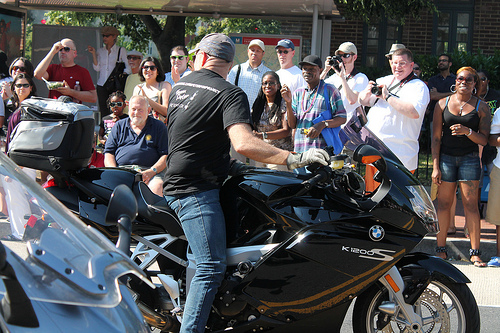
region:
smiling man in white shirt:
[359, 45, 426, 185]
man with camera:
[322, 41, 367, 104]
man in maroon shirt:
[40, 32, 97, 106]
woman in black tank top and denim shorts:
[432, 68, 492, 272]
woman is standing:
[435, 59, 492, 269]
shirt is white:
[369, 74, 431, 164]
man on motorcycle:
[18, 14, 475, 331]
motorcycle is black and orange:
[39, 97, 477, 332]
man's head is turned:
[146, 36, 302, 330]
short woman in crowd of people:
[247, 72, 297, 139]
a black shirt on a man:
[157, 68, 249, 195]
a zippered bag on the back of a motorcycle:
[5, 97, 99, 177]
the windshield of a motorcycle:
[0, 146, 162, 309]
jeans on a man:
[162, 191, 229, 331]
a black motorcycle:
[40, 135, 481, 326]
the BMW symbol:
[365, 220, 389, 245]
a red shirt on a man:
[40, 60, 98, 106]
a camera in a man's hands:
[324, 54, 347, 72]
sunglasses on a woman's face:
[140, 61, 157, 71]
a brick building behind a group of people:
[281, 2, 495, 98]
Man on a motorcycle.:
[91, 34, 496, 332]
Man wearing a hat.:
[171, 29, 281, 120]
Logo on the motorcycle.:
[342, 184, 404, 256]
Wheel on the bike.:
[338, 252, 460, 324]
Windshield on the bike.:
[320, 118, 469, 244]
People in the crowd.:
[34, 25, 208, 145]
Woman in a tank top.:
[435, 29, 496, 262]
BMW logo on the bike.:
[327, 209, 404, 281]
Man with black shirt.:
[162, 52, 279, 223]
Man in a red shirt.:
[23, 27, 114, 131]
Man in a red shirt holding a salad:
[32, 36, 97, 103]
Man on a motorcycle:
[0, 32, 481, 332]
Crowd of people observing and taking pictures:
[0, 32, 497, 265]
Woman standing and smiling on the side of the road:
[427, 65, 489, 268]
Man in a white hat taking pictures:
[317, 40, 366, 128]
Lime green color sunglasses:
[168, 53, 188, 61]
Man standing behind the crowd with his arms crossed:
[426, 53, 458, 165]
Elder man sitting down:
[102, 95, 169, 199]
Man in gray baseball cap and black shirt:
[161, 34, 331, 331]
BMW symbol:
[367, 221, 385, 244]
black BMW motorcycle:
[18, 123, 450, 331]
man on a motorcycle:
[76, 22, 456, 331]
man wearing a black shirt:
[143, 29, 309, 331]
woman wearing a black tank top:
[428, 60, 488, 279]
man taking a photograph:
[357, 37, 427, 169]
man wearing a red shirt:
[31, 35, 95, 101]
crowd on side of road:
[10, 33, 495, 165]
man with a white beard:
[106, 93, 166, 167]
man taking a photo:
[323, 37, 368, 107]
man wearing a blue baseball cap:
[266, 30, 299, 80]